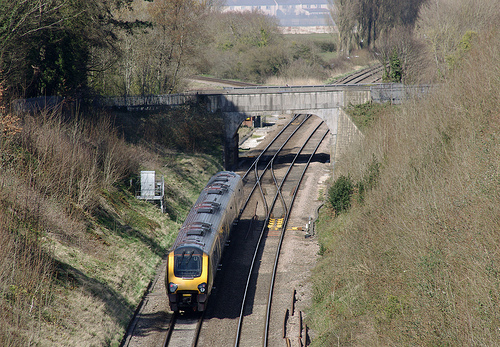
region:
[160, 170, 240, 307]
black and yellow train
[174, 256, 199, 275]
wind shield on train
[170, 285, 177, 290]
head light on train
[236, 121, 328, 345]
wood and metal train tracks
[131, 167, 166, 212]
grey electrical box on ground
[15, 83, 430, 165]
grey stone bridge over tracks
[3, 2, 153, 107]
tree with green leaves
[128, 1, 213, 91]
tree with no leaves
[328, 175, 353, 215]
green bush by tracks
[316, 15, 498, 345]
brown weeds on hill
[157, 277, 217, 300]
Lights on front of train.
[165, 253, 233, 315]
Yellow section on train car.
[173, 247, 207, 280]
Black wipers on window.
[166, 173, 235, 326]
Train cars driving on tracks.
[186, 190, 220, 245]
Top of train is black.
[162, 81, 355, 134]
Bridge over top of train tracks.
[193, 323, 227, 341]
Gravel near and under train tracks.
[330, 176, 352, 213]
Green leaves on tree near tracks.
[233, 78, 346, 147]
Bridge over tracks is gray.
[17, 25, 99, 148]
Large trees near train tracks.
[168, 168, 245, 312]
a yellow and black train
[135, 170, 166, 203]
a silver power box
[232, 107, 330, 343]
a row of train tracks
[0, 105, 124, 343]
a row of brown trees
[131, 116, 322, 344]
a yellow train on the train tracks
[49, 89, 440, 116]
a white concrete bridge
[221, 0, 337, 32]
a town in the distance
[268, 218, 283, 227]
a yellow spot on the train tracks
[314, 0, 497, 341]
a woody hill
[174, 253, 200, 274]
the front windshield on a train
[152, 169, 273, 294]
yellow train on track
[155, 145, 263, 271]
top of train is silver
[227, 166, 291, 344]
train tracks are brown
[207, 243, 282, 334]
brown gravel between tracks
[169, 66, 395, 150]
grey bridge over tracks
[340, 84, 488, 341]
brown grass on hill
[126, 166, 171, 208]
grey box next to train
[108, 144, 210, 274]
green grass on hill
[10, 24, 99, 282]
sparse trees and bushes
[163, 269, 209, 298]
white headlights on train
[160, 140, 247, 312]
Train on train tracks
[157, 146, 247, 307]
This is a train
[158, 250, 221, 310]
Train has yellow front piece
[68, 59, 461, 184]
Cement bridge above train tracks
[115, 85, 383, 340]
There are two train tracks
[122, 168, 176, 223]
Power box next to tracks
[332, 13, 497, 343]
Hill next to train tracks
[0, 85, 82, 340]
Dry shrubbery next to train tracks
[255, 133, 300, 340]
One empty train track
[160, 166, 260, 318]
Train is silver and yellow